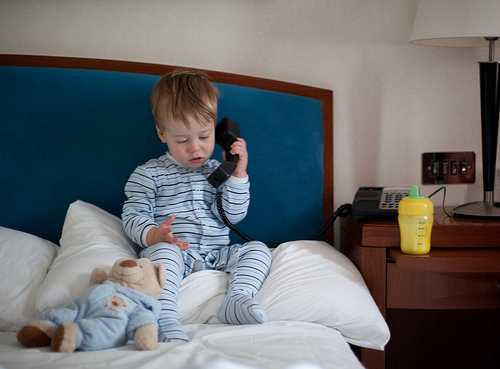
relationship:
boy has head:
[118, 66, 270, 346] [147, 66, 219, 169]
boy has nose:
[118, 66, 270, 346] [185, 138, 203, 155]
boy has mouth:
[118, 66, 270, 346] [186, 155, 206, 165]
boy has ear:
[118, 66, 270, 346] [152, 123, 168, 145]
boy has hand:
[118, 66, 270, 346] [222, 136, 249, 177]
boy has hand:
[118, 66, 270, 346] [143, 211, 190, 251]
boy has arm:
[118, 66, 270, 346] [119, 164, 158, 248]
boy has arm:
[118, 66, 270, 346] [211, 158, 249, 230]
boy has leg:
[118, 66, 270, 346] [213, 238, 272, 328]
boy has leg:
[118, 66, 270, 346] [136, 241, 190, 348]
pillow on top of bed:
[33, 197, 392, 354] [1, 50, 368, 368]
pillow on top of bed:
[1, 222, 63, 335] [1, 50, 368, 368]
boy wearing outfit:
[118, 66, 270, 346] [118, 151, 270, 342]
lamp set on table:
[407, 0, 499, 224] [335, 200, 498, 368]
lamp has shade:
[407, 0, 499, 224] [404, 0, 498, 52]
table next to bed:
[335, 200, 498, 368] [1, 50, 368, 368]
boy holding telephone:
[118, 66, 270, 346] [208, 115, 422, 252]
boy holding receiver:
[118, 66, 270, 346] [206, 115, 242, 188]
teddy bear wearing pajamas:
[13, 253, 168, 353] [45, 278, 161, 350]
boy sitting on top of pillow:
[118, 66, 270, 346] [33, 197, 392, 354]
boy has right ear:
[118, 66, 270, 346] [152, 123, 168, 145]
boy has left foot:
[118, 66, 270, 346] [215, 290, 265, 328]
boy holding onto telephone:
[118, 66, 270, 346] [208, 115, 422, 252]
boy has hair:
[118, 66, 270, 346] [148, 65, 219, 133]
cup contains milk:
[393, 183, 435, 256] [398, 220, 432, 255]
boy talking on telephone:
[118, 66, 270, 346] [208, 115, 422, 252]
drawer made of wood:
[382, 239, 499, 314] [382, 244, 498, 312]